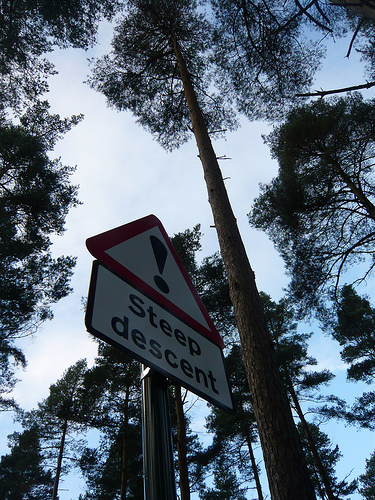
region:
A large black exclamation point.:
[145, 232, 174, 298]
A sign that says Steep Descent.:
[85, 260, 235, 411]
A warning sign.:
[83, 214, 236, 417]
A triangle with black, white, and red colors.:
[84, 213, 226, 352]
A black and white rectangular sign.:
[84, 258, 236, 412]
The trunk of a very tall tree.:
[162, 31, 319, 498]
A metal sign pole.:
[137, 357, 178, 498]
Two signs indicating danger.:
[82, 213, 235, 412]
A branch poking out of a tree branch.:
[209, 148, 231, 164]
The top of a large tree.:
[87, 0, 247, 155]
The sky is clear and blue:
[26, 316, 80, 364]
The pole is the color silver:
[136, 400, 180, 498]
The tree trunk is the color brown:
[230, 311, 321, 495]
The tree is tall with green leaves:
[246, 24, 373, 255]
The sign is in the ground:
[73, 203, 246, 491]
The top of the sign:
[79, 216, 238, 412]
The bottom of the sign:
[125, 394, 204, 497]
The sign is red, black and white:
[77, 204, 237, 421]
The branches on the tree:
[316, 187, 374, 283]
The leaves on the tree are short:
[4, 126, 61, 306]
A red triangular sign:
[87, 213, 225, 350]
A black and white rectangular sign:
[93, 265, 237, 414]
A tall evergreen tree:
[138, 2, 320, 497]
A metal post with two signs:
[81, 202, 237, 498]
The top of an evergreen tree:
[335, 285, 374, 391]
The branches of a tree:
[105, 3, 232, 140]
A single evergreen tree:
[41, 355, 84, 498]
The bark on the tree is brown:
[255, 385, 309, 498]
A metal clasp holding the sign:
[138, 368, 156, 381]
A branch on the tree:
[59, 485, 72, 493]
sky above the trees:
[74, 138, 142, 191]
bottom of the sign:
[129, 393, 195, 471]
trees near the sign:
[25, 400, 108, 475]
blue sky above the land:
[89, 135, 134, 173]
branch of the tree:
[231, 380, 308, 466]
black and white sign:
[100, 295, 227, 391]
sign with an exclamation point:
[115, 219, 192, 298]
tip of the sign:
[125, 201, 190, 242]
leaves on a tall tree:
[264, 188, 299, 224]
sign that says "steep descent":
[105, 289, 230, 398]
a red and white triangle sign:
[86, 214, 225, 347]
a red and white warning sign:
[85, 212, 224, 347]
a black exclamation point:
[150, 234, 169, 293]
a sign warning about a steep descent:
[86, 261, 233, 412]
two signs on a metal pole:
[86, 212, 233, 498]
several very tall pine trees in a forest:
[1, 2, 374, 498]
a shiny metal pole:
[138, 367, 177, 498]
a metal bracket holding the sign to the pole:
[139, 367, 155, 379]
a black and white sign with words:
[87, 261, 233, 412]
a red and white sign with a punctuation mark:
[85, 212, 225, 346]